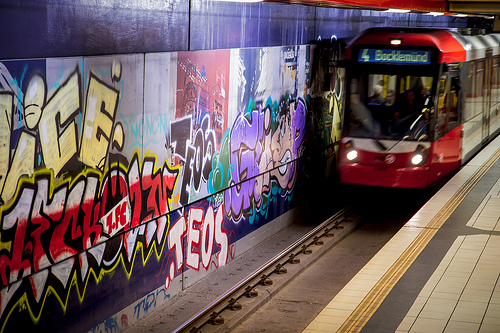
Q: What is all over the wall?
A: Graffiti.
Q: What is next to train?
A: Yellow line.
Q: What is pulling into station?
A: Train.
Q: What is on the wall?
A: Paint.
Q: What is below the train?
A: A track.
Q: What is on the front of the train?
A: Lights.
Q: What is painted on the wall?
A: Graffiti.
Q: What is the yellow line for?
A: Inform passengers to stand behind yellow line.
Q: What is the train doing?
A: Moving.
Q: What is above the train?
A: Writing.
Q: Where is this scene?
A: A train/subway station.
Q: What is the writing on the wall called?
A: Graffiti.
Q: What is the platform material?
A: Tile.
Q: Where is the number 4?
A: Front left of train.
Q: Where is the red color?
A: Front of train.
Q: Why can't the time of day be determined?
A: Scene appears to be in a subway tunnel.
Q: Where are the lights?
A: On the front of the train.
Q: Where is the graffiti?
A: On the wall.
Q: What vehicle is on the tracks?
A: A train.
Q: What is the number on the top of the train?
A: 4.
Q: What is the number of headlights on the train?
A: 2.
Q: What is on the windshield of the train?
A: Wiper blades.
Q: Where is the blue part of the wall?
A: Above the graffiti.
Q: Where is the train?
A: Tunnel.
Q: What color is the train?
A: Red.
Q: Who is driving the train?
A: Driver.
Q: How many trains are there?
A: One.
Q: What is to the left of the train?
A: Wall.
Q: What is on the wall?
A: Graffiti.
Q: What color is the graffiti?
A: Purple.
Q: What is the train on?
A: Tracks.